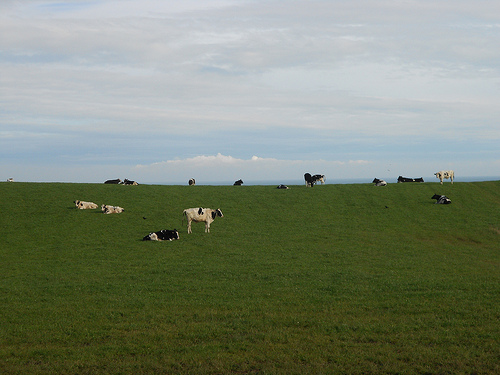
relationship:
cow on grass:
[182, 207, 224, 234] [0, 182, 500, 373]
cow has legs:
[177, 192, 238, 234] [182, 219, 212, 235]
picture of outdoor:
[1, 3, 496, 373] [7, 1, 497, 368]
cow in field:
[143, 229, 180, 243] [0, 180, 499, 373]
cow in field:
[182, 207, 224, 234] [0, 180, 499, 373]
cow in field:
[101, 204, 125, 215] [0, 180, 499, 373]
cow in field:
[73, 200, 99, 210] [0, 180, 499, 373]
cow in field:
[435, 163, 457, 184] [0, 180, 499, 373]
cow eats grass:
[182, 207, 224, 234] [0, 182, 500, 373]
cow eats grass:
[143, 229, 180, 243] [0, 182, 500, 373]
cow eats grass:
[101, 204, 125, 215] [0, 182, 500, 373]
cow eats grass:
[73, 200, 99, 210] [0, 182, 500, 373]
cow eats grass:
[434, 170, 454, 185] [0, 182, 500, 373]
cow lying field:
[182, 207, 224, 234] [0, 180, 499, 373]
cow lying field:
[143, 229, 180, 243] [0, 180, 499, 373]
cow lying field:
[101, 204, 125, 215] [0, 180, 499, 373]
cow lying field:
[73, 200, 99, 210] [0, 180, 499, 373]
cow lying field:
[431, 194, 452, 204] [0, 180, 499, 373]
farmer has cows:
[5, 173, 17, 186] [63, 157, 494, 277]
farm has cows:
[6, 180, 496, 373] [34, 49, 499, 279]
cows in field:
[73, 169, 454, 242] [0, 180, 499, 373]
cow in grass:
[143, 229, 180, 243] [0, 182, 500, 373]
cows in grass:
[77, 187, 127, 222] [257, 286, 299, 326]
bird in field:
[128, 202, 159, 227] [173, 171, 458, 347]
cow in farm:
[182, 207, 224, 234] [0, 183, 500, 375]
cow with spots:
[182, 207, 224, 234] [193, 207, 207, 215]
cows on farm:
[145, 200, 225, 245] [0, 183, 500, 375]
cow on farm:
[427, 190, 454, 207] [0, 183, 500, 375]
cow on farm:
[143, 229, 180, 243] [0, 183, 500, 375]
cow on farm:
[97, 201, 127, 216] [0, 183, 500, 375]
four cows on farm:
[33, 178, 226, 264] [0, 183, 500, 375]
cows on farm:
[53, 75, 460, 297] [0, 183, 500, 375]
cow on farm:
[182, 207, 224, 234] [0, 183, 500, 375]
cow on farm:
[101, 204, 125, 215] [0, 183, 500, 375]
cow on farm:
[72, 198, 96, 210] [0, 183, 500, 375]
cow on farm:
[431, 194, 452, 204] [0, 183, 500, 375]